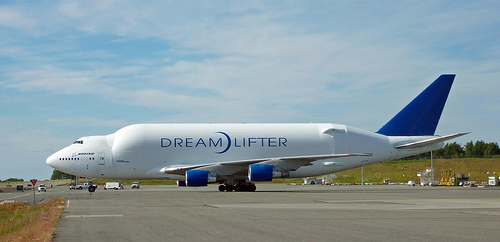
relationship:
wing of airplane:
[160, 144, 370, 182] [41, 70, 472, 193]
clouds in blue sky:
[0, 2, 495, 176] [0, 0, 500, 179]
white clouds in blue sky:
[224, 33, 308, 99] [5, 3, 495, 60]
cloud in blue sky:
[8, 55, 199, 104] [0, 0, 500, 179]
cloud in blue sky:
[9, 3, 419, 130] [0, 0, 500, 179]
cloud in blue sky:
[413, 57, 499, 157] [0, 0, 500, 179]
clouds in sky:
[228, 47, 298, 84] [115, 36, 151, 56]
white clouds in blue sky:
[207, 27, 377, 90] [0, 0, 500, 179]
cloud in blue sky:
[13, 58, 137, 96] [0, 0, 500, 179]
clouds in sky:
[94, 60, 170, 100] [97, 25, 164, 77]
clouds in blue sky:
[1, 10, 486, 130] [0, 0, 500, 179]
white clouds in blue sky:
[267, 37, 332, 77] [83, 33, 146, 60]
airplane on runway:
[41, 70, 472, 196] [57, 190, 497, 240]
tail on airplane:
[387, 63, 457, 152] [42, 56, 480, 195]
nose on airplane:
[42, 130, 106, 180] [41, 70, 472, 196]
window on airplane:
[57, 157, 64, 159] [45, 74, 467, 189]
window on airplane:
[71, 140, 82, 147] [45, 74, 467, 189]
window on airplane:
[86, 156, 93, 163] [45, 74, 467, 189]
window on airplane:
[90, 153, 96, 163] [45, 74, 467, 189]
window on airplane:
[75, 155, 81, 163] [45, 74, 467, 189]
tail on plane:
[378, 63, 458, 150] [64, 67, 489, 214]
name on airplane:
[157, 133, 295, 149] [41, 70, 472, 193]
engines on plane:
[245, 153, 280, 188] [28, 66, 479, 193]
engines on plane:
[179, 156, 209, 195] [28, 66, 479, 193]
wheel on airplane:
[217, 184, 225, 191] [41, 70, 472, 193]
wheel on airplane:
[85, 181, 95, 193] [41, 70, 472, 193]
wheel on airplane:
[217, 181, 225, 191] [41, 70, 472, 193]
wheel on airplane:
[222, 182, 235, 191] [41, 70, 472, 193]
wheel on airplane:
[246, 182, 256, 192] [41, 70, 472, 193]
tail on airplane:
[378, 63, 458, 150] [41, 70, 472, 193]